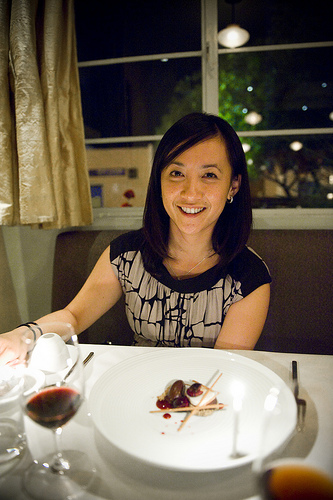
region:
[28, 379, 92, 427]
the wine is red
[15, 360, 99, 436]
the wine is red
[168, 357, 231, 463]
small dessert on plate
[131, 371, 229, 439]
small dessert on plate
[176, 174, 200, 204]
the nose of a woman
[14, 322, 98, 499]
a wine glass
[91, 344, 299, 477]
a white plate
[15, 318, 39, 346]
a woman's black bracelet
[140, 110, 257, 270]
a woman's black hair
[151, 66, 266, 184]
a large green tree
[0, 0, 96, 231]
part of a brown curtain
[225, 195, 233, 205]
a woman's silver earring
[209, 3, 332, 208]
part of a window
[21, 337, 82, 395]
a wine glass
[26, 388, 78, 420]
red liquid in the wine glass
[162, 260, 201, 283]
women is wearing a necklace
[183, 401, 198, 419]
chopsticks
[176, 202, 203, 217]
the women is smiling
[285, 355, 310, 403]
a fork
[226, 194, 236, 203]
women is wearing an earring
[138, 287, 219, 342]
a brown and black blouse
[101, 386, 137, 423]
the plate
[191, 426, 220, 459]
the plate is white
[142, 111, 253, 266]
the woman's black hair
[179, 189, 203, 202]
the woman's nose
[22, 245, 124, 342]
the woman's right arm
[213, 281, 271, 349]
the woman's left arm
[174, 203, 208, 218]
the woman's smile and teeth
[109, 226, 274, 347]
the woman's black and white top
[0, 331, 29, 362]
the woman's right hand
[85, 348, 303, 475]
white plate with food on it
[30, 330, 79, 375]
coffee mug up side down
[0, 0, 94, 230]
gold curtains behind the woman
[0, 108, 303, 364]
woman sitting at a table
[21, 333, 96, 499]
wine glass with a little bit of dark liquid in it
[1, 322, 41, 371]
hand resting on the table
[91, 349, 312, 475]
white plate with a little bit of food on it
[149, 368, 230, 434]
two toothpicks on the plate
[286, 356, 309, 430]
fork laying beside the plate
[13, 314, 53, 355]
two black bands around the arm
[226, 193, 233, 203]
silver hoop earring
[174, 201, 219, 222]
smile that shows teeth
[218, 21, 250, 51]
reflection on the window